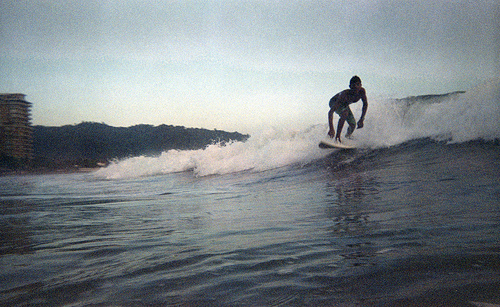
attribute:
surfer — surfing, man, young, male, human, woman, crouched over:
[325, 72, 370, 146]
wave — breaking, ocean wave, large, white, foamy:
[84, 73, 497, 190]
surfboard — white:
[315, 136, 361, 152]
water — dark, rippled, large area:
[4, 98, 487, 303]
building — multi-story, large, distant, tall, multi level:
[1, 80, 36, 171]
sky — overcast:
[2, 2, 498, 133]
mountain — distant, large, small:
[25, 109, 229, 168]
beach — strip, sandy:
[2, 165, 104, 184]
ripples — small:
[68, 234, 405, 303]